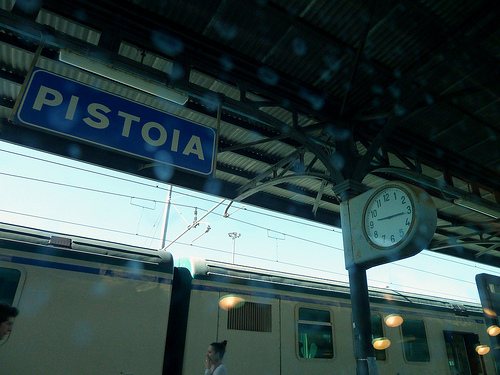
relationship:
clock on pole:
[359, 182, 414, 248] [348, 266, 373, 373]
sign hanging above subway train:
[12, 66, 217, 179] [0, 220, 500, 375]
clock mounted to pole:
[359, 182, 421, 250] [328, 172, 379, 372]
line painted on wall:
[133, 265, 180, 304] [94, 252, 179, 339]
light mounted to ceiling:
[453, 197, 498, 221] [1, 1, 496, 267]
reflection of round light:
[200, 279, 497, 369] [381, 311, 406, 328]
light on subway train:
[381, 311, 406, 328] [0, 220, 500, 375]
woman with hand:
[201, 336, 236, 373] [203, 353, 212, 368]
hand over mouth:
[203, 353, 212, 368] [208, 353, 213, 361]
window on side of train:
[292, 300, 336, 360] [1, 242, 498, 374]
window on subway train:
[292, 300, 340, 365] [0, 220, 500, 375]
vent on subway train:
[225, 297, 274, 335] [0, 220, 500, 375]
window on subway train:
[292, 300, 336, 360] [0, 213, 498, 371]